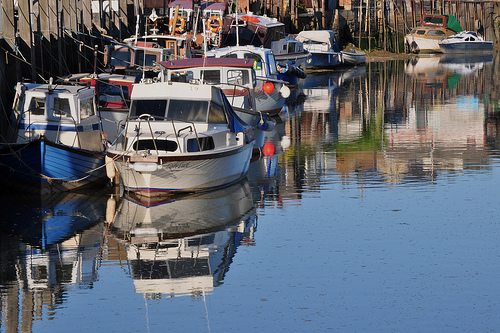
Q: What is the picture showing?
A: It is showing a lake.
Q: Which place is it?
A: It is a lake.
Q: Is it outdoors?
A: Yes, it is outdoors.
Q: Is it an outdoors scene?
A: Yes, it is outdoors.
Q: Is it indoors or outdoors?
A: It is outdoors.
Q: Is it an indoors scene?
A: No, it is outdoors.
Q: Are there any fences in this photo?
A: No, there are no fences.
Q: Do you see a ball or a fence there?
A: No, there are no fences or balls.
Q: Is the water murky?
A: Yes, the water is murky.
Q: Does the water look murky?
A: Yes, the water is murky.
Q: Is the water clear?
A: No, the water is murky.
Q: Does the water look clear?
A: No, the water is murky.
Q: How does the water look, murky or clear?
A: The water is murky.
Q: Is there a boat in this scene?
A: Yes, there is a boat.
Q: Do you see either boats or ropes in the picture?
A: Yes, there is a boat.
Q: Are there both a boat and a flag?
A: No, there is a boat but no flags.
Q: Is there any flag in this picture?
A: No, there are no flags.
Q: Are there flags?
A: No, there are no flags.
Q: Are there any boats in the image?
A: Yes, there is a boat.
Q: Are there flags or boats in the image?
A: Yes, there is a boat.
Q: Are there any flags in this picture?
A: No, there are no flags.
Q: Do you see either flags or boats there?
A: Yes, there is a boat.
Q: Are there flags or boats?
A: Yes, there is a boat.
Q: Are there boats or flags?
A: Yes, there is a boat.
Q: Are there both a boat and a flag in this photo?
A: No, there is a boat but no flags.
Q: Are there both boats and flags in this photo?
A: No, there is a boat but no flags.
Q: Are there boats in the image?
A: Yes, there is a boat.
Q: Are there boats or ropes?
A: Yes, there is a boat.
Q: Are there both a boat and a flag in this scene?
A: No, there is a boat but no flags.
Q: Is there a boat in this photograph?
A: Yes, there is a boat.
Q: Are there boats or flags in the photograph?
A: Yes, there is a boat.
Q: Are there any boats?
A: Yes, there is a boat.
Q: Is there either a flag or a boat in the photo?
A: Yes, there is a boat.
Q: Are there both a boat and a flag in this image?
A: No, there is a boat but no flags.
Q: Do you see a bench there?
A: No, there are no benches.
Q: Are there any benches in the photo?
A: No, there are no benches.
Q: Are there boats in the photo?
A: Yes, there is a boat.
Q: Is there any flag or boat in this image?
A: Yes, there is a boat.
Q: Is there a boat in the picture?
A: Yes, there is a boat.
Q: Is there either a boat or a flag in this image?
A: Yes, there is a boat.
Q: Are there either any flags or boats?
A: Yes, there is a boat.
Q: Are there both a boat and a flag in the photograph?
A: No, there is a boat but no flags.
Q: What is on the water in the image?
A: The boat is on the water.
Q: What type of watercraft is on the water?
A: The watercraft is a boat.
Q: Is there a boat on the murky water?
A: Yes, there is a boat on the water.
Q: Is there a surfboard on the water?
A: No, there is a boat on the water.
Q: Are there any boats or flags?
A: Yes, there is a boat.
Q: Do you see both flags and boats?
A: No, there is a boat but no flags.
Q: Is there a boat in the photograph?
A: Yes, there is a boat.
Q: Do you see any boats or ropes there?
A: Yes, there is a boat.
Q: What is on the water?
A: The boat is on the water.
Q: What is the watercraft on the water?
A: The watercraft is a boat.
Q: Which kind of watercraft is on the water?
A: The watercraft is a boat.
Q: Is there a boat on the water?
A: Yes, there is a boat on the water.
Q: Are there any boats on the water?
A: Yes, there is a boat on the water.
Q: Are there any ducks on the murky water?
A: No, there is a boat on the water.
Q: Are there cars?
A: No, there are no cars.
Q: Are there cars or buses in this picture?
A: No, there are no cars or buses.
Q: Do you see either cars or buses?
A: No, there are no cars or buses.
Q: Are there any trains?
A: No, there are no trains.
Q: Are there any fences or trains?
A: No, there are no trains or fences.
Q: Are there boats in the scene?
A: Yes, there is a boat.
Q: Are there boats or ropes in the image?
A: Yes, there is a boat.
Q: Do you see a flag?
A: No, there are no flags.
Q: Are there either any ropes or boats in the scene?
A: Yes, there is a boat.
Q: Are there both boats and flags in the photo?
A: No, there is a boat but no flags.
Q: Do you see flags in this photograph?
A: No, there are no flags.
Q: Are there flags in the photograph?
A: No, there are no flags.